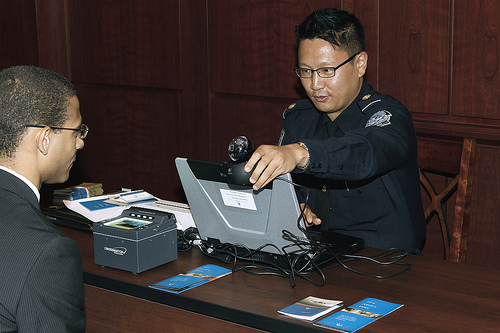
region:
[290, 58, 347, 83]
Man wearing prescribed glasses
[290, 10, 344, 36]
Man has black hair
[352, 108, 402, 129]
Blue symbol on dark blue shirt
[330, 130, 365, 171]
Man wears dark blue shirt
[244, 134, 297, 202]
Mans hand on laptop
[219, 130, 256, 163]
Camera on top of laptop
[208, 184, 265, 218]
White label on laptop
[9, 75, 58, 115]
Man has low hair cut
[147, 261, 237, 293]
Blue panthlet on table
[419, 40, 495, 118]
Burgandy brownish pant on walls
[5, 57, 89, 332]
young man wearing business suit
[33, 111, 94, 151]
wire framed eye classes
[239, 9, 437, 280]
Asian man wearing security uniform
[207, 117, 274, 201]
round web cam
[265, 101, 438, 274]
navy blue security guard uniform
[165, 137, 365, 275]
silver and black laptop computer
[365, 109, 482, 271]
brown wooden chair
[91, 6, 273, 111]
dark wood wall paneling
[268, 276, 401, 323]
light blue and white literature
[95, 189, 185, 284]
small gray box on desk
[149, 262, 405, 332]
three pamphlets on a wooden desk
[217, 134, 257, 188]
a black cam connected to the laptop computer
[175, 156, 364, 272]
a grey and black laptop computer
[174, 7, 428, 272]
a man in black uniform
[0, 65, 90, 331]
a man in a blue suit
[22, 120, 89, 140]
eyeglasses on the man's eyes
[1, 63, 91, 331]
a man getting a photo taken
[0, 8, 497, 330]
man in blue uniform taking a picture of a man in a business suit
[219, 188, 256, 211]
a white sticker on the back of the laptop's monitor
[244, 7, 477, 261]
an employee in uniform sitting in a wooden chair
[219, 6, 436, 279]
Official taking a photo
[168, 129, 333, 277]
Camera connected to a computer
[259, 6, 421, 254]
Man in a uniform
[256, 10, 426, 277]
Man with dark hair and glasses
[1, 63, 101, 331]
Man in a dark suit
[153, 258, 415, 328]
Three pamphlets on a desk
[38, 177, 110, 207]
Stack of pamphlets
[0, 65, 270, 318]
Man getting his picture taken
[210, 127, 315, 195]
Hand holding a camera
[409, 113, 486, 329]
Wood chair and table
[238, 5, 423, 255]
a uniformed police officer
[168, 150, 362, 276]
a black and silver laptop computer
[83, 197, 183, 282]
a grey metal box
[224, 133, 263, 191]
a black web cam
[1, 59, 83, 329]
a man wearing a dark suit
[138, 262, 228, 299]
a blue phamplet on desk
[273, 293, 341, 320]
a blue phamplet on desk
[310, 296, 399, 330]
a blue phamplet on desk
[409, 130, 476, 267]
wooden chair back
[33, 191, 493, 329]
a dark wood desk